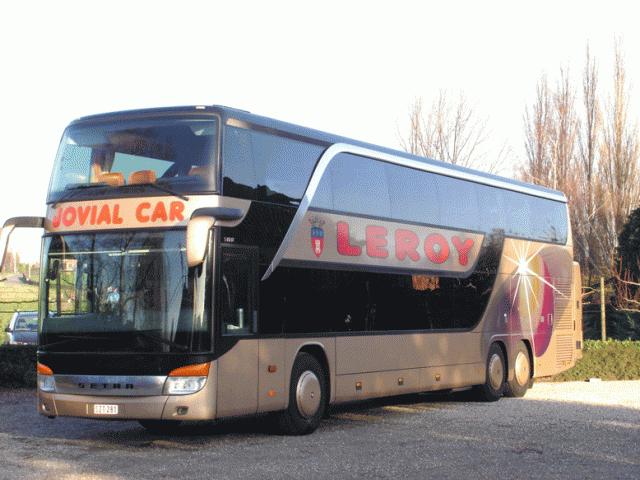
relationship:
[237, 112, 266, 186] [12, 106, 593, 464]
window on bus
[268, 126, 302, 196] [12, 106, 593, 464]
window on bus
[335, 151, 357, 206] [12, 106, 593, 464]
window on bus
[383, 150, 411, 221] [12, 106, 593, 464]
window on bus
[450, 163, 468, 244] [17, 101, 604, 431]
window on bus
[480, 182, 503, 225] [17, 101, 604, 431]
window on bus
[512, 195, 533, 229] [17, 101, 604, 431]
window on bus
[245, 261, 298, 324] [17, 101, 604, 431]
window on bus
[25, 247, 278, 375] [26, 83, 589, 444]
window on bus